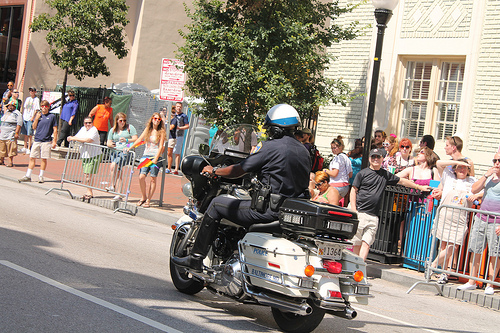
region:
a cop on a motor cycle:
[167, 100, 384, 331]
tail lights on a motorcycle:
[304, 263, 381, 279]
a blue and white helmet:
[262, 101, 301, 134]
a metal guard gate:
[42, 141, 140, 214]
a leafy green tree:
[173, 0, 356, 124]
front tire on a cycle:
[171, 226, 207, 299]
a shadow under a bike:
[191, 295, 361, 332]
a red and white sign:
[157, 57, 192, 100]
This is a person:
[135, 108, 167, 218]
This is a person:
[103, 106, 133, 214]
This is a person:
[24, 97, 57, 192]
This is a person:
[164, 95, 185, 172]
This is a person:
[426, 148, 473, 303]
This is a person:
[345, 140, 400, 290]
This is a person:
[168, 101, 320, 288]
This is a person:
[15, 97, 60, 192]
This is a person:
[0, 96, 21, 179]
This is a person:
[53, 82, 82, 159]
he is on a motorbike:
[119, 85, 336, 302]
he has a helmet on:
[270, 88, 321, 137]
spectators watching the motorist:
[9, 100, 486, 217]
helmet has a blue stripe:
[257, 113, 310, 133]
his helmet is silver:
[266, 93, 303, 118]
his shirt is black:
[363, 168, 398, 198]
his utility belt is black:
[240, 176, 286, 210]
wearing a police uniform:
[230, 135, 302, 229]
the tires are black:
[152, 236, 201, 303]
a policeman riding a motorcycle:
[183, 106, 392, 329]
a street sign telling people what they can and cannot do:
[153, 44, 198, 157]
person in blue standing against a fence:
[52, 73, 84, 143]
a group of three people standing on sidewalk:
[63, 100, 174, 216]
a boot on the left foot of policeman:
[169, 211, 234, 284]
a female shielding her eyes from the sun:
[438, 145, 480, 270]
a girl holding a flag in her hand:
[133, 105, 174, 206]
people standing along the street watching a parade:
[8, 80, 498, 222]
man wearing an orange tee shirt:
[86, 92, 114, 144]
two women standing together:
[106, 109, 167, 208]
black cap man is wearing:
[368, 146, 386, 158]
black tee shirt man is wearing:
[349, 165, 399, 219]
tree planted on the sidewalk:
[173, 0, 372, 156]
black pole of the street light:
[361, 0, 399, 165]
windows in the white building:
[392, 53, 464, 140]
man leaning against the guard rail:
[349, 147, 433, 259]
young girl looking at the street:
[322, 135, 352, 208]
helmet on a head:
[243, 91, 292, 140]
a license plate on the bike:
[317, 233, 349, 266]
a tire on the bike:
[268, 263, 335, 331]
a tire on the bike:
[167, 230, 211, 289]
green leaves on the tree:
[203, 22, 287, 93]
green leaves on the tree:
[298, 37, 350, 122]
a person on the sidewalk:
[446, 151, 468, 244]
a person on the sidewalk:
[381, 135, 420, 199]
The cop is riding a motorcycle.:
[170, 102, 391, 329]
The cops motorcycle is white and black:
[164, 98, 374, 328]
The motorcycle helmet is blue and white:
[260, 99, 304, 138]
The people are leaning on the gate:
[55, 107, 169, 222]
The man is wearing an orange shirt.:
[84, 93, 116, 140]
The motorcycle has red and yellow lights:
[167, 100, 380, 318]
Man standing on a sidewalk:
[30, 99, 59, 180]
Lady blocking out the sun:
[432, 156, 474, 284]